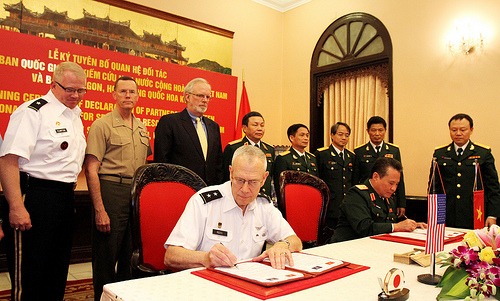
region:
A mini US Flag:
[422, 192, 445, 252]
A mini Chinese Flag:
[465, 182, 487, 229]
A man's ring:
[278, 249, 288, 257]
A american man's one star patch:
[26, 94, 47, 119]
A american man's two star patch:
[200, 186, 226, 202]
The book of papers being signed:
[200, 247, 360, 297]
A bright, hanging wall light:
[416, 8, 499, 69]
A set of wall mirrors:
[298, 18, 399, 68]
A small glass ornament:
[372, 265, 415, 297]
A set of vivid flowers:
[432, 234, 497, 299]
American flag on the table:
[419, 172, 446, 278]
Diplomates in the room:
[10, 16, 498, 299]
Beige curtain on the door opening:
[326, 87, 384, 116]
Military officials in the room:
[250, 100, 488, 204]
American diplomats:
[19, 59, 261, 274]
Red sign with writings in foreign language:
[12, 35, 174, 83]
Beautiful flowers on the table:
[443, 225, 494, 300]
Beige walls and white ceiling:
[231, 0, 323, 52]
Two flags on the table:
[402, 188, 492, 273]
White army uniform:
[13, 95, 83, 186]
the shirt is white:
[224, 218, 274, 252]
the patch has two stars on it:
[196, 188, 223, 202]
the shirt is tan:
[103, 131, 131, 152]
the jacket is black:
[163, 128, 183, 143]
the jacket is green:
[328, 158, 353, 193]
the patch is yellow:
[273, 148, 295, 160]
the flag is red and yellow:
[465, 178, 488, 240]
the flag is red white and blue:
[418, 190, 457, 274]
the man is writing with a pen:
[212, 236, 252, 277]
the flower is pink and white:
[449, 240, 481, 272]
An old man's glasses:
[232, 178, 264, 188]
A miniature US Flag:
[419, 192, 451, 257]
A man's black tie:
[451, 144, 465, 159]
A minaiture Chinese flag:
[470, 193, 491, 228]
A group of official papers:
[215, 264, 288, 284]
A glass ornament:
[376, 266, 408, 293]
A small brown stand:
[412, 265, 444, 292]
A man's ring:
[277, 251, 289, 255]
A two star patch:
[198, 187, 227, 207]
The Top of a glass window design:
[302, 19, 392, 71]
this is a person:
[169, 142, 299, 277]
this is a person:
[326, 153, 406, 246]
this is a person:
[0, 62, 93, 289]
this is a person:
[88, 70, 144, 286]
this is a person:
[147, 75, 227, 188]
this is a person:
[222, 105, 277, 206]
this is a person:
[275, 111, 313, 216]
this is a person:
[320, 105, 353, 206]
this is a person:
[350, 110, 410, 206]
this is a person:
[429, 87, 496, 239]